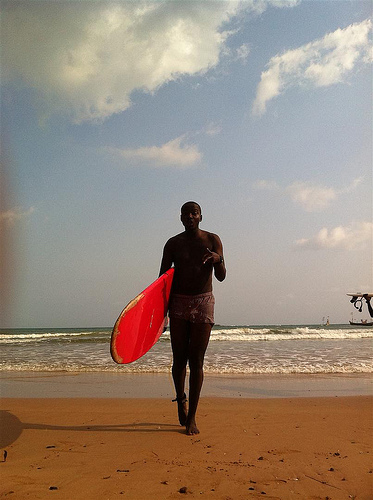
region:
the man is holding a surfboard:
[114, 201, 225, 440]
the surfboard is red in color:
[108, 255, 179, 368]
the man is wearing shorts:
[171, 292, 216, 327]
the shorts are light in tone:
[171, 292, 218, 325]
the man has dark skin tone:
[156, 200, 227, 448]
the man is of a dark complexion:
[154, 202, 228, 438]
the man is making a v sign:
[199, 243, 221, 265]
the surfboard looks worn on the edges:
[111, 293, 147, 366]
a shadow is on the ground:
[0, 407, 202, 456]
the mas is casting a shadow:
[4, 200, 226, 454]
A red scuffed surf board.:
[104, 259, 177, 377]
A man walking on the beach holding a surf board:
[100, 193, 229, 451]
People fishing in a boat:
[340, 310, 371, 333]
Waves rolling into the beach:
[0, 318, 372, 398]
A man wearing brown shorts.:
[154, 197, 230, 437]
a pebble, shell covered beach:
[1, 387, 369, 498]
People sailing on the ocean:
[315, 313, 333, 331]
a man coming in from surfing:
[110, 200, 228, 434]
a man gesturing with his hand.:
[155, 201, 232, 438]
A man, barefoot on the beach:
[109, 200, 257, 438]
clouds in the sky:
[250, 48, 364, 102]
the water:
[256, 334, 329, 369]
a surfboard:
[114, 314, 150, 361]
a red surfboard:
[116, 317, 150, 357]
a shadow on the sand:
[15, 410, 118, 434]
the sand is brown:
[230, 415, 294, 455]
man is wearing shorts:
[169, 294, 213, 322]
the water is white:
[13, 330, 48, 340]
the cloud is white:
[135, 148, 199, 170]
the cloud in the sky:
[117, 144, 204, 177]